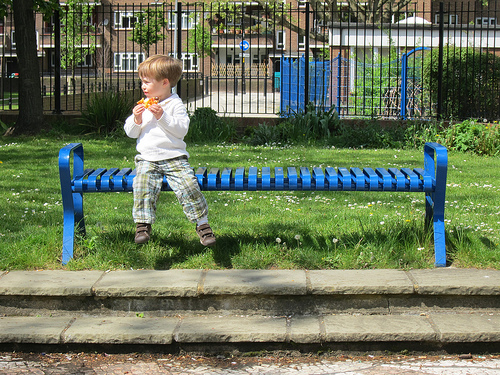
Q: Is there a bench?
A: Yes, there is a bench.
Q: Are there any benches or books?
A: Yes, there is a bench.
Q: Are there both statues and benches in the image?
A: No, there is a bench but no statues.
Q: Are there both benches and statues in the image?
A: No, there is a bench but no statues.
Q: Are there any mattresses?
A: No, there are no mattresses.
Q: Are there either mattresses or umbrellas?
A: No, there are no mattresses or umbrellas.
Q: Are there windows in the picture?
A: Yes, there is a window.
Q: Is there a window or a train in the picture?
A: Yes, there is a window.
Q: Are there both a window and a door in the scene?
A: No, there is a window but no doors.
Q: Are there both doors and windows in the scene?
A: No, there is a window but no doors.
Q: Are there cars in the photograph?
A: No, there are no cars.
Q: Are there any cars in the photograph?
A: No, there are no cars.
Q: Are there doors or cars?
A: No, there are no cars or doors.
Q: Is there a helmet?
A: No, there are no helmets.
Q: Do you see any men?
A: No, there are no men.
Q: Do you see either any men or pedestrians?
A: No, there are no men or pedestrians.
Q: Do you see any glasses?
A: No, there are no glasses.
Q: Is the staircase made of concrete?
A: Yes, the staircase is made of concrete.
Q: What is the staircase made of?
A: The staircase is made of concrete.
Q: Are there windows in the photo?
A: Yes, there is a window.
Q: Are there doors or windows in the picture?
A: Yes, there is a window.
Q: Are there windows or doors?
A: Yes, there is a window.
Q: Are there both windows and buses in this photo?
A: No, there is a window but no buses.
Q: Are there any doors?
A: No, there are no doors.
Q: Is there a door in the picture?
A: No, there are no doors.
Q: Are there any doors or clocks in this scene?
A: No, there are no doors or clocks.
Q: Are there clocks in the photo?
A: No, there are no clocks.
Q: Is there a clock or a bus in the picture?
A: No, there are no clocks or buses.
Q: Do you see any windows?
A: Yes, there is a window.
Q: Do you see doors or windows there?
A: Yes, there is a window.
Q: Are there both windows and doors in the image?
A: No, there is a window but no doors.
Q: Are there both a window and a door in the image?
A: No, there is a window but no doors.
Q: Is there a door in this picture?
A: No, there are no doors.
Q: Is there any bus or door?
A: No, there are no doors or buses.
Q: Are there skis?
A: No, there are no skis.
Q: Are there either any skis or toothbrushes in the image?
A: No, there are no skis or toothbrushes.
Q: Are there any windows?
A: Yes, there is a window.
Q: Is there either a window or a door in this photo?
A: Yes, there is a window.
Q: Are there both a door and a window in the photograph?
A: No, there is a window but no doors.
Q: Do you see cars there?
A: No, there are no cars.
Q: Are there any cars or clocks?
A: No, there are no cars or clocks.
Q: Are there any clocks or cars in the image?
A: No, there are no cars or clocks.